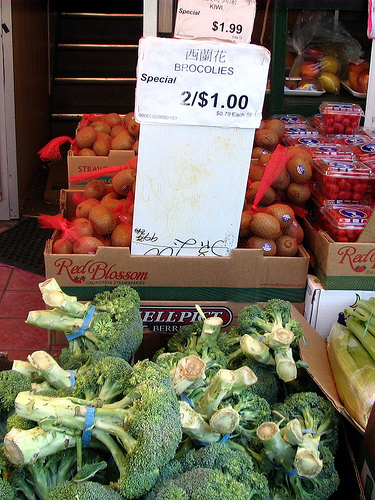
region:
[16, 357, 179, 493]
the broccoli is laying in the box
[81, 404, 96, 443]
the broccoli is in a strap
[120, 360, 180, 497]
the broccoli is green in color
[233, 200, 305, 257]
the kiwis are in a bag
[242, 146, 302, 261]
the bag is orange in color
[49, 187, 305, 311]
the kiwis are in a box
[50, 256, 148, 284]
the lettering is red in color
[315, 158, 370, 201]
the strawberries are in a container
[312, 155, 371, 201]
the container is transparent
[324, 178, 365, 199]
the strawberries are red in color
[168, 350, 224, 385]
brown edge of broccoli stalk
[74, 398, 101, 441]
blue rubber band on vegetable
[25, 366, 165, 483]
bunches of broccoli stalks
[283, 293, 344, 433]
edge of brown box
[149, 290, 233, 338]
red and white words on box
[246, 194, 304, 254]
box full of kiwi fruits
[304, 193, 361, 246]
clear tub of red tomatoes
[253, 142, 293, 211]
orange tie on fruit mesh holder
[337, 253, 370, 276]
small strawberry on brown box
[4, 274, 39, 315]
red tiles on the floor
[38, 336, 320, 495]
Heads broccoli ready sell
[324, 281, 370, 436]
Green celery stalks available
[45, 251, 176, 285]
Cardboard box Red Blossom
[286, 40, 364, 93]
Bagged miscellaneous fruit veggies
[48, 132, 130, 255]
Kiwi red netted bags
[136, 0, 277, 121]
Sale signs Kiwi and Broccoli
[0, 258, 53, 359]
Area red tiled flooring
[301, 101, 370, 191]
Plastic containers Grape Tomatoes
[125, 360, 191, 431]
Head broccoli slightly ripe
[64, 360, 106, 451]
Blue elastic bands secure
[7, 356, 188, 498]
broccoli is green and lush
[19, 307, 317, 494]
a pile of broccoli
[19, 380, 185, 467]
a single broccoli head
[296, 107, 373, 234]
a large display of cherry tomatoes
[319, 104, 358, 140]
a container of cherry tomatoes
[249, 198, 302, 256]
a bag of kiwis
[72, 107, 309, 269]
a large shipment of bags of kiwis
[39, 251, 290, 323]
a cardboard box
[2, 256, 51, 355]
a red tile floor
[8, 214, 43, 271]
a black floor mat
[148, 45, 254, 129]
a pricing sign